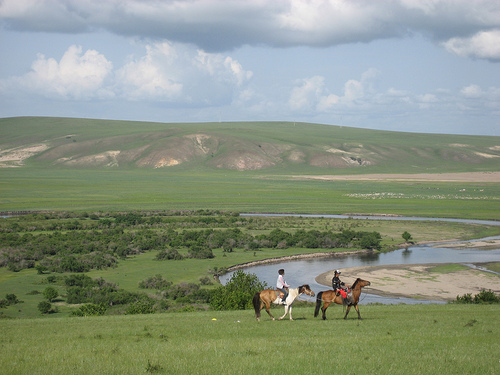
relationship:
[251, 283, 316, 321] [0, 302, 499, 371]
horse walking on grass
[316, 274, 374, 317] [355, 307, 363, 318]
horse has a leg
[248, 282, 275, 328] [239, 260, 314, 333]
tail of horse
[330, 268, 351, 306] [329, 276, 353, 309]
man in pants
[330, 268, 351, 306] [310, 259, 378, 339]
man riding horse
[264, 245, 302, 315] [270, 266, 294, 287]
man in shirt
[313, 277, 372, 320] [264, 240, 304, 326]
horse carrying man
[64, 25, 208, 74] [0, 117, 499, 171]
clouds over mountain range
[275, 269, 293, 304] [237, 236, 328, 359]
man on horse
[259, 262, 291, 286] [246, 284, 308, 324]
woman on horse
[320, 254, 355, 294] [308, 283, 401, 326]
man on horse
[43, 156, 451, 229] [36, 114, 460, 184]
area by mountain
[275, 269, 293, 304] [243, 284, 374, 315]
man on horses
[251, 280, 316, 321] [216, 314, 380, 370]
horse in grass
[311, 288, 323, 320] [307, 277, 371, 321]
tail on horse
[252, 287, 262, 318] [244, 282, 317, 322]
tail on horse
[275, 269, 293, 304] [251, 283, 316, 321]
man riding horse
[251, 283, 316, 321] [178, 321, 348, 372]
horse on grass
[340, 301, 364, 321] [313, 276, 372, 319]
legs on horse